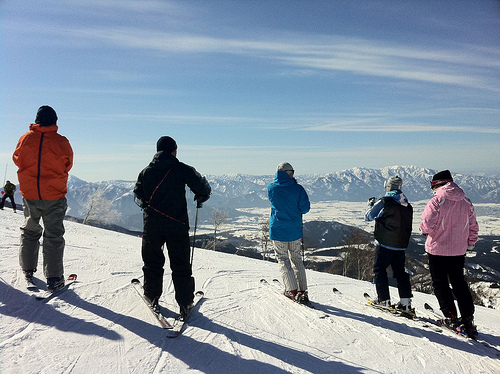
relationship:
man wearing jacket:
[13, 105, 75, 299] [10, 120, 73, 202]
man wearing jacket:
[130, 133, 212, 338] [132, 150, 211, 225]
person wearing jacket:
[258, 162, 311, 306] [262, 167, 311, 242]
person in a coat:
[418, 159, 490, 340] [418, 182, 478, 257]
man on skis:
[13, 105, 75, 299] [8, 253, 93, 318]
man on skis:
[130, 133, 212, 338] [132, 260, 221, 361]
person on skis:
[258, 155, 307, 225] [270, 270, 340, 326]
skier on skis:
[363, 175, 418, 322] [370, 297, 475, 349]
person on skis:
[418, 169, 479, 340] [370, 297, 475, 349]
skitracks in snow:
[199, 295, 253, 345] [199, 266, 397, 369]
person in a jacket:
[418, 169, 479, 340] [423, 195, 479, 258]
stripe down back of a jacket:
[25, 133, 54, 193] [7, 115, 81, 227]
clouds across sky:
[239, 26, 493, 98] [187, 17, 496, 191]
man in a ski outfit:
[130, 133, 212, 338] [130, 157, 226, 291]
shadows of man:
[163, 330, 299, 371] [130, 133, 212, 338]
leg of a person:
[30, 199, 75, 289] [8, 90, 93, 184]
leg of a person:
[14, 199, 55, 291] [7, 95, 88, 180]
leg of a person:
[165, 217, 197, 307] [125, 130, 230, 231]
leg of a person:
[136, 220, 172, 307] [121, 120, 211, 212]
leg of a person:
[270, 233, 302, 294] [248, 148, 331, 242]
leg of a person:
[281, 239, 308, 284] [254, 153, 343, 209]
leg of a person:
[361, 246, 410, 311] [368, 166, 426, 231]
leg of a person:
[383, 248, 419, 302] [361, 175, 428, 245]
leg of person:
[428, 254, 460, 337] [415, 162, 491, 347]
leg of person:
[455, 255, 482, 348] [415, 162, 491, 347]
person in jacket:
[258, 162, 311, 306] [262, 169, 311, 241]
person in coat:
[418, 169, 479, 340] [415, 179, 483, 261]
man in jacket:
[13, 98, 81, 298] [10, 123, 73, 198]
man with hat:
[128, 129, 213, 331] [153, 133, 179, 157]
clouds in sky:
[290, 26, 478, 92] [187, 17, 438, 136]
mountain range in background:
[56, 160, 494, 209] [11, 15, 493, 267]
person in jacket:
[418, 169, 479, 340] [419, 181, 486, 260]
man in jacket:
[13, 105, 75, 299] [10, 118, 81, 207]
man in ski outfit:
[130, 133, 212, 338] [130, 161, 212, 309]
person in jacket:
[258, 162, 311, 306] [265, 169, 316, 239]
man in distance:
[1, 175, 25, 213] [2, 163, 495, 234]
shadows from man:
[2, 276, 493, 372] [13, 105, 75, 299]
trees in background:
[64, 185, 288, 240] [4, 160, 494, 298]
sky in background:
[187, 17, 438, 136] [3, 1, 498, 222]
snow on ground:
[199, 309, 370, 368] [22, 320, 479, 367]